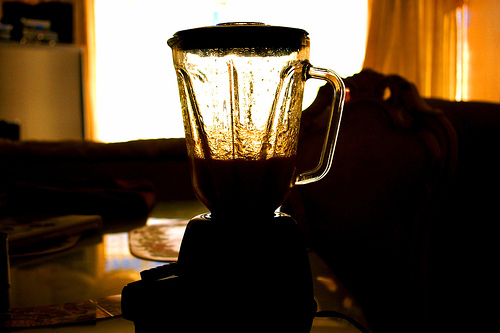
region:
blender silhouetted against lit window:
[117, 18, 352, 326]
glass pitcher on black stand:
[163, 20, 350, 216]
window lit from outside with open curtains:
[85, 0, 462, 137]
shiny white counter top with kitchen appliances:
[7, 179, 379, 331]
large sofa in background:
[6, 71, 495, 246]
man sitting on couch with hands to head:
[297, 68, 442, 213]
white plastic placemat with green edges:
[125, 219, 192, 269]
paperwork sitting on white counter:
[24, 293, 136, 331]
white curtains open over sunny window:
[360, 1, 482, 111]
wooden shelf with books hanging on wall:
[6, 7, 79, 52]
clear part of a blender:
[166, 15, 354, 216]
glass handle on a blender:
[304, 54, 348, 196]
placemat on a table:
[105, 211, 210, 269]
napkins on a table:
[24, 268, 107, 332]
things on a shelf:
[25, 11, 74, 51]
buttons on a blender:
[127, 258, 201, 292]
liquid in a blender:
[187, 134, 302, 219]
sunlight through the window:
[89, 38, 179, 128]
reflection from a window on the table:
[66, 226, 156, 299]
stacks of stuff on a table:
[27, 204, 122, 279]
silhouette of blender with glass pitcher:
[111, 19, 358, 330]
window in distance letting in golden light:
[84, 0, 457, 127]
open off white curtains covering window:
[368, 0, 475, 105]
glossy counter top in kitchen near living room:
[17, 218, 359, 322]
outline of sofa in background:
[10, 63, 499, 227]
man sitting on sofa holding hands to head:
[297, 58, 445, 235]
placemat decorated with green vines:
[126, 218, 199, 265]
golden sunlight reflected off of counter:
[89, 208, 193, 323]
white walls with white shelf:
[7, 0, 92, 141]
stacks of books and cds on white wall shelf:
[1, 14, 62, 44]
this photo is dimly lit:
[12, 18, 444, 303]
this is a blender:
[163, 33, 419, 328]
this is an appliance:
[156, 22, 284, 253]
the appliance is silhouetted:
[152, 44, 334, 319]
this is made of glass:
[190, 40, 284, 148]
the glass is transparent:
[203, 63, 277, 135]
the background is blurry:
[26, 46, 133, 196]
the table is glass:
[34, 234, 103, 330]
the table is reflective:
[24, 256, 126, 318]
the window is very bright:
[91, 5, 186, 157]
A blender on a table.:
[119, 20, 345, 331]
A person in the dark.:
[300, 66, 461, 164]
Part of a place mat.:
[128, 219, 189, 260]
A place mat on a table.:
[127, 220, 190, 264]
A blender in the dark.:
[119, 20, 345, 331]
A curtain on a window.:
[361, 2, 469, 102]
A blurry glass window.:
[92, 3, 470, 145]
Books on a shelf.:
[1, 3, 81, 54]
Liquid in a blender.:
[119, 18, 346, 330]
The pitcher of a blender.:
[166, 20, 343, 221]